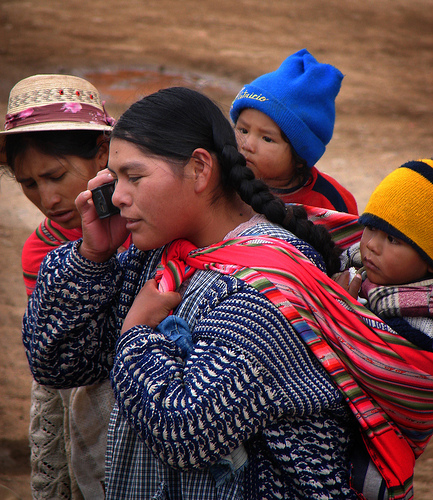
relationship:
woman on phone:
[24, 84, 373, 484] [93, 181, 118, 228]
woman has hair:
[24, 84, 373, 484] [110, 81, 345, 275]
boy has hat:
[225, 50, 365, 269] [229, 50, 344, 163]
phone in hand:
[93, 181, 118, 228] [73, 162, 129, 258]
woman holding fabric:
[24, 84, 373, 484] [150, 236, 431, 496]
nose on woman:
[108, 180, 137, 212] [24, 84, 373, 484]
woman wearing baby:
[24, 84, 373, 484] [331, 160, 432, 461]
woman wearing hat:
[0, 73, 151, 477] [2, 67, 111, 145]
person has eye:
[24, 84, 373, 484] [124, 173, 144, 185]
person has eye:
[26, 85, 396, 499] [124, 173, 144, 185]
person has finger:
[26, 85, 396, 499] [71, 189, 92, 212]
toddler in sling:
[335, 151, 433, 415] [140, 228, 431, 493]